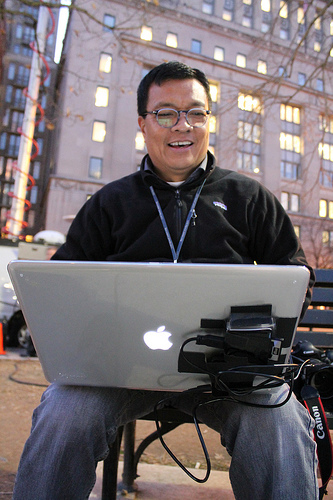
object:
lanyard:
[145, 180, 205, 263]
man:
[13, 60, 320, 500]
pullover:
[49, 150, 315, 315]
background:
[0, 1, 332, 268]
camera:
[282, 339, 333, 499]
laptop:
[5, 255, 310, 396]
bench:
[96, 265, 333, 500]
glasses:
[144, 106, 208, 128]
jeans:
[16, 382, 318, 499]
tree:
[95, 0, 331, 268]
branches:
[284, 0, 333, 73]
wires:
[153, 335, 300, 484]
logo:
[142, 325, 173, 352]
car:
[8, 307, 33, 348]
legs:
[101, 410, 125, 500]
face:
[146, 85, 210, 170]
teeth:
[176, 142, 179, 146]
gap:
[178, 142, 180, 146]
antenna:
[4, 0, 52, 242]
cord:
[5, 5, 55, 240]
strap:
[302, 393, 332, 485]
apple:
[142, 325, 173, 353]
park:
[0, 298, 333, 500]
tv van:
[17, 225, 65, 267]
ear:
[137, 116, 146, 139]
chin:
[165, 151, 196, 175]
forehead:
[147, 79, 208, 111]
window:
[253, 92, 263, 115]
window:
[293, 132, 303, 154]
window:
[318, 197, 327, 218]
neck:
[144, 161, 211, 184]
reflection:
[160, 118, 174, 129]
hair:
[135, 61, 213, 121]